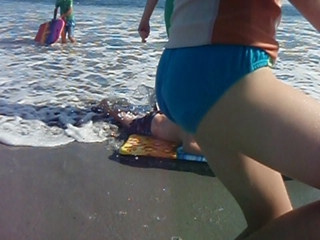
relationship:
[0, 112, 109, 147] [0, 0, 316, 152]
foam in water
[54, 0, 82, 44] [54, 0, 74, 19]
man wearing green shirt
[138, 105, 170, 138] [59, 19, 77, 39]
butt holding swimming trunks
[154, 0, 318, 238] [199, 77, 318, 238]
surfer has leg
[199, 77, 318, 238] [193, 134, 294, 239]
leg has leg